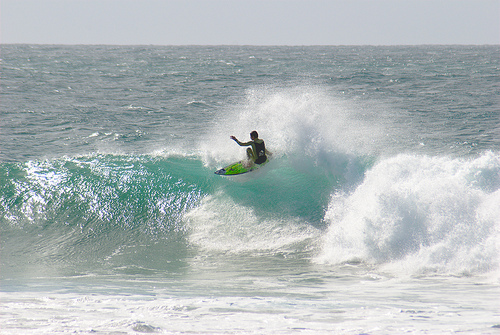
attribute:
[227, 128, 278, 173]
person — surfing, riding, looking away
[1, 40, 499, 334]
ocean — wavy, blue, white, whiting, calm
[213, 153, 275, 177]
surfboard — neon green, green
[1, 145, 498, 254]
wave — large, big, blue, green, cresting, clear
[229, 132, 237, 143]
hand — in the air, up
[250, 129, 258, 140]
hair — short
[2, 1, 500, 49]
sky — clear, blue, gray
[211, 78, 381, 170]
splash — big